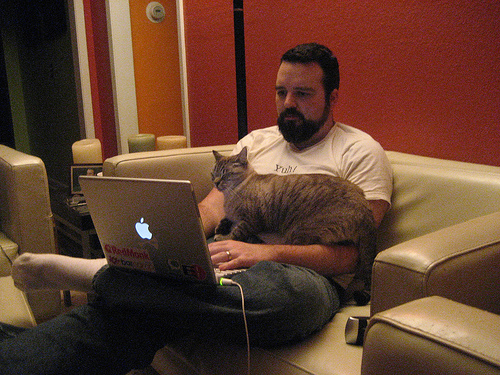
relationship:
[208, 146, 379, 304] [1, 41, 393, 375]
cat on man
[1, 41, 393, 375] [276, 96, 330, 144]
man has beard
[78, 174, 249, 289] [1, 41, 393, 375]
laptop on man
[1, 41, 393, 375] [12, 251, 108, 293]
man wearing sock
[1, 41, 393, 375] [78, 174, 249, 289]
man using laptop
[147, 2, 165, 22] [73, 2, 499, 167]
alarm on wall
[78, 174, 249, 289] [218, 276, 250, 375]
laptop has cord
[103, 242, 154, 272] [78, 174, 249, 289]
sticker on laptop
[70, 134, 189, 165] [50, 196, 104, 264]
candles are on table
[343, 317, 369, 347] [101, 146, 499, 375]
remote on chair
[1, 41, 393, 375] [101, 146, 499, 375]
man on chair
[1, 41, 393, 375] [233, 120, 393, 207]
man wearing shirt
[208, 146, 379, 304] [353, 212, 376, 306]
cat has tail